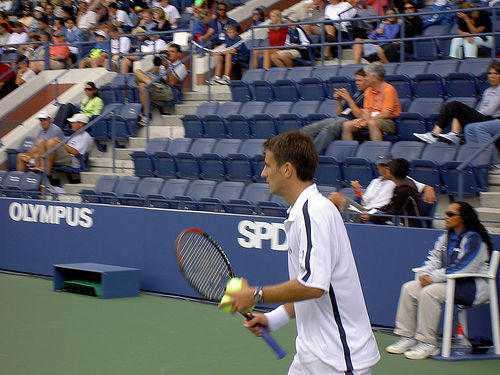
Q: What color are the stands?
A: Blue.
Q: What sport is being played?
A: Tennis.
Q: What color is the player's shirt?
A: White.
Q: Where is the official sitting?
A: On the side of the court.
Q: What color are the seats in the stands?
A: Blue.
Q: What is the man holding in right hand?
A: A tennis racket.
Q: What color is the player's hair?
A: Brown.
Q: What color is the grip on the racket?
A: Blue.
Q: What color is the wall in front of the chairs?
A: Blue.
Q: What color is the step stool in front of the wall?
A: Blue.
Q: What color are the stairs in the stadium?
A: Silver.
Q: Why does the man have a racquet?
A: To hit the balls.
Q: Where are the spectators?
A: Stands.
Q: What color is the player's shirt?
A: White.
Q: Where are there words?
A: Blue wall.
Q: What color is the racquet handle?
A: Blue.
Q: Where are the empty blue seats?
A: Stands.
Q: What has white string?
A: Racquet.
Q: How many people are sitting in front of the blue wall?
A: 1.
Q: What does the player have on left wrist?
A: Watch.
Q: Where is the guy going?
A: Play tennis.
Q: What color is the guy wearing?
A: White.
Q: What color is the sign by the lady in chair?
A: Blue.